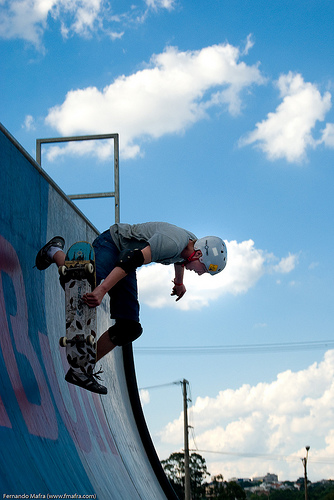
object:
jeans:
[92, 226, 141, 349]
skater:
[34, 220, 228, 395]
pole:
[183, 378, 193, 499]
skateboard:
[59, 238, 98, 386]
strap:
[180, 252, 199, 269]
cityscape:
[203, 471, 334, 500]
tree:
[159, 450, 210, 499]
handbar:
[34, 130, 120, 233]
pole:
[113, 133, 120, 227]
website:
[0, 491, 101, 500]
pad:
[107, 319, 142, 349]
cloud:
[237, 68, 333, 170]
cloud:
[154, 347, 334, 485]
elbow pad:
[114, 247, 145, 274]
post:
[303, 458, 309, 499]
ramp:
[0, 123, 183, 498]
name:
[0, 491, 32, 500]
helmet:
[193, 234, 228, 278]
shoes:
[35, 236, 66, 271]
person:
[35, 221, 229, 396]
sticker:
[207, 262, 218, 271]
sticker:
[203, 238, 209, 256]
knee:
[126, 320, 144, 342]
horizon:
[160, 470, 334, 500]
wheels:
[86, 332, 97, 349]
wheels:
[85, 261, 96, 275]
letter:
[0, 234, 60, 443]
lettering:
[0, 239, 119, 456]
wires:
[135, 379, 182, 391]